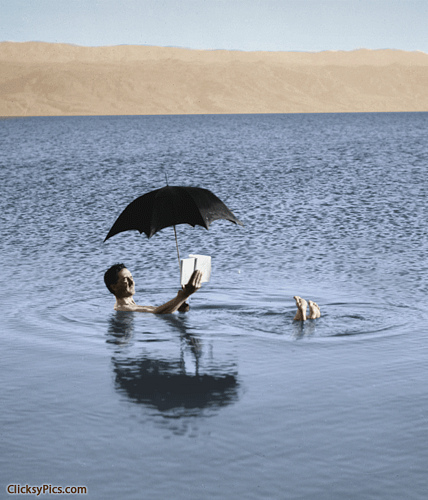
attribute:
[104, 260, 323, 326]
person — shaded, reading, sitting, laying, floating, light skinned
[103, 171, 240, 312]
umbrella — black, shading, open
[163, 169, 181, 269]
pole — silver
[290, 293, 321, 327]
feet — sticking up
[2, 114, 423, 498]
water — blue, rippled, ripply, dark blue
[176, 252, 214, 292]
book — white, held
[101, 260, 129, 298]
hair — dark, short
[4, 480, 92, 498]
clicksypics.com — written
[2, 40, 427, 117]
sand — brown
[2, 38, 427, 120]
mountains — brown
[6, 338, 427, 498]
water — smooth, blue, calm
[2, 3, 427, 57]
sky — light, blue, clear, daytime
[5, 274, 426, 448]
light — reflected